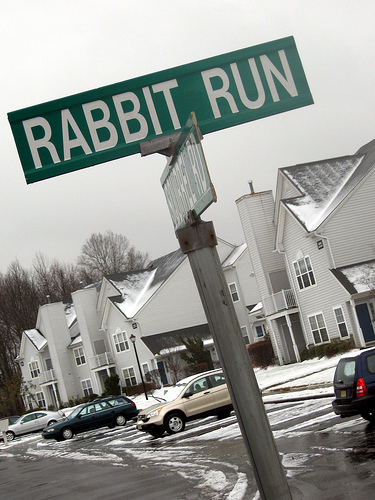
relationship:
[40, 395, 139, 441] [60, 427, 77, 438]
car has tire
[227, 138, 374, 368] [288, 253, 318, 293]
building has window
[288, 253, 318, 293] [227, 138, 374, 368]
window on building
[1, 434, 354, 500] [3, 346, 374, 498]
snow on ground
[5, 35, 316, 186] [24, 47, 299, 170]
sign says rabbit run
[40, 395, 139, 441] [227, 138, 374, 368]
car parked in front of building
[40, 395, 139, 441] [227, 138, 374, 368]
car parked near building